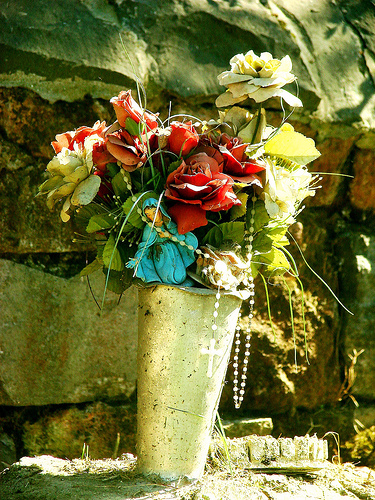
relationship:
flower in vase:
[164, 120, 267, 237] [134, 282, 255, 480]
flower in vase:
[257, 154, 323, 225] [134, 282, 255, 480]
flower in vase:
[100, 126, 150, 173] [122, 272, 245, 488]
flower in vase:
[215, 49, 303, 108] [87, 274, 277, 482]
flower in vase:
[164, 120, 267, 237] [87, 274, 277, 482]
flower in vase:
[31, 132, 112, 229] [87, 274, 277, 482]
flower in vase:
[126, 117, 277, 192] [129, 260, 231, 491]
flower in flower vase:
[164, 120, 267, 237] [135, 276, 242, 484]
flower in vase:
[37, 101, 295, 266] [114, 269, 249, 499]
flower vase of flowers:
[135, 276, 242, 484] [114, 123, 243, 246]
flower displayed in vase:
[211, 47, 302, 107] [134, 282, 255, 480]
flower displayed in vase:
[164, 120, 267, 237] [134, 282, 255, 480]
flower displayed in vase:
[34, 141, 102, 223] [134, 282, 255, 480]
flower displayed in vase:
[105, 88, 160, 172] [134, 282, 255, 480]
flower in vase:
[164, 120, 267, 237] [132, 273, 248, 481]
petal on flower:
[168, 203, 207, 234] [164, 120, 267, 237]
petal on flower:
[218, 145, 242, 173] [164, 120, 267, 237]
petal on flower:
[241, 160, 265, 174] [164, 120, 267, 237]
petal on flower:
[177, 171, 210, 184] [164, 120, 267, 237]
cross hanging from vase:
[197, 337, 226, 379] [91, 221, 289, 475]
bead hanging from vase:
[233, 329, 242, 341] [132, 273, 248, 481]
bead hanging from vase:
[228, 356, 239, 361] [132, 273, 248, 481]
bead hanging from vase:
[233, 371, 242, 379] [132, 273, 248, 481]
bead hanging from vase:
[228, 383, 241, 397] [132, 273, 248, 481]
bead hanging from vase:
[236, 402, 241, 411] [132, 273, 248, 481]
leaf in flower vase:
[85, 216, 113, 232] [135, 276, 242, 484]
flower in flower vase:
[215, 49, 303, 108] [135, 276, 242, 484]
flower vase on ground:
[135, 276, 242, 484] [0, 438, 373, 499]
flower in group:
[164, 120, 267, 237] [42, 49, 322, 293]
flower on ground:
[164, 120, 267, 237] [4, 425, 374, 497]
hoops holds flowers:
[129, 141, 186, 194] [33, 85, 320, 299]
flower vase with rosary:
[135, 276, 242, 484] [191, 236, 271, 418]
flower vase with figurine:
[135, 276, 242, 484] [125, 198, 199, 287]